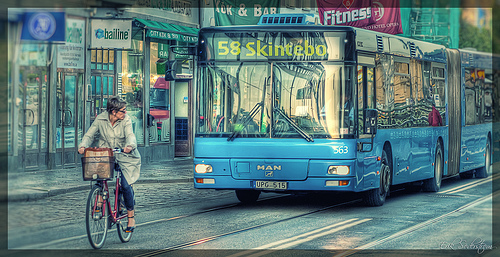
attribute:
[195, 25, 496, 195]
bus — blue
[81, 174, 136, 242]
bike — red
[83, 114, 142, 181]
jacket — tan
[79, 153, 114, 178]
basket — tan, brown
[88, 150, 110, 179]
bag — brown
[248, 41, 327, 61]
words — yellow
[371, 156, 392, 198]
tire — black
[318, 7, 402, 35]
advertising sign — red